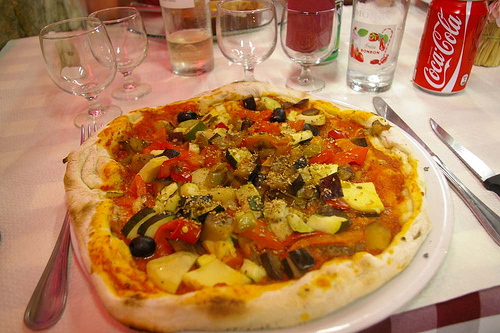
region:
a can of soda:
[408, 0, 487, 97]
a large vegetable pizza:
[64, 79, 433, 326]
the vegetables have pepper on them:
[129, 98, 402, 283]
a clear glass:
[34, 16, 124, 122]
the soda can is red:
[410, 0, 491, 95]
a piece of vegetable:
[340, 178, 384, 215]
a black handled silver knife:
[433, 109, 498, 197]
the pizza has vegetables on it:
[64, 77, 432, 327]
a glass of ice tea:
[160, 0, 210, 75]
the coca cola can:
[411, 0, 483, 94]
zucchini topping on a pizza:
[115, 200, 160, 237]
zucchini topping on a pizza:
[135, 206, 172, 236]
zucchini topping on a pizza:
[277, 251, 302, 278]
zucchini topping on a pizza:
[335, 175, 385, 215]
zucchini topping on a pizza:
[181, 117, 206, 144]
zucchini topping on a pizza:
[287, 127, 319, 147]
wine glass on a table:
[35, 15, 124, 133]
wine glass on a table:
[82, 4, 154, 106]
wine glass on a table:
[210, 1, 282, 87]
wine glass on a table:
[269, 0, 348, 91]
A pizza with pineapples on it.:
[150, 114, 292, 289]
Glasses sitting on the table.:
[28, 24, 164, 96]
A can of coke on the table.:
[423, 0, 468, 106]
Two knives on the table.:
[377, 89, 497, 230]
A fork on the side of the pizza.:
[55, 118, 99, 315]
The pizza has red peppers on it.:
[146, 203, 213, 265]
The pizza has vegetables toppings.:
[166, 131, 359, 275]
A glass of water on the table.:
[152, 3, 227, 84]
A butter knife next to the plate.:
[368, 92, 490, 241]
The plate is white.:
[332, 98, 459, 288]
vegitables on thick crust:
[2, 65, 476, 332]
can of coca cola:
[414, 0, 494, 100]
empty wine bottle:
[353, 0, 435, 93]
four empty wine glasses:
[16, 3, 397, 145]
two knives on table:
[362, 95, 496, 274]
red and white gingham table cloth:
[349, 275, 499, 330]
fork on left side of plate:
[0, 78, 471, 314]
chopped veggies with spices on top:
[56, 43, 482, 310]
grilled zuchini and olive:
[126, 203, 180, 270]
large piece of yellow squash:
[308, 169, 398, 221]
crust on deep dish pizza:
[184, 282, 274, 312]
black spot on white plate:
[417, 247, 436, 260]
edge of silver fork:
[20, 236, 88, 328]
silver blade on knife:
[426, 110, 498, 169]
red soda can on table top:
[417, 58, 474, 100]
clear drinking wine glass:
[46, 73, 127, 127]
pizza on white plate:
[53, 75, 440, 303]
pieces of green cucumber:
[118, 208, 195, 237]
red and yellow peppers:
[131, 132, 221, 169]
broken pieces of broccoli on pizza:
[180, 157, 299, 212]